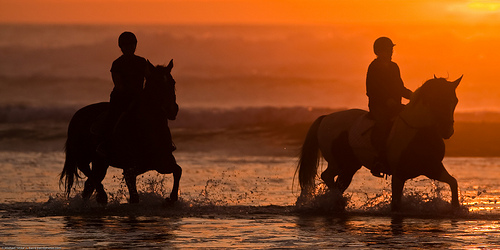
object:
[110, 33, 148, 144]
person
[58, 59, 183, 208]
horse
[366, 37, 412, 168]
person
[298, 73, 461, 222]
horse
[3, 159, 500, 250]
water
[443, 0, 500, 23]
sun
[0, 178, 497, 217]
wave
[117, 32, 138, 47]
helmet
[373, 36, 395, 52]
helmet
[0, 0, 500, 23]
sky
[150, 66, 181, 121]
face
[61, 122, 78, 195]
tail